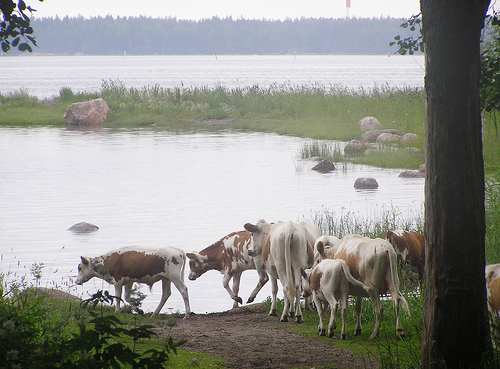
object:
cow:
[75, 245, 191, 321]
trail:
[216, 326, 228, 335]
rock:
[68, 221, 100, 233]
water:
[109, 203, 125, 224]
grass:
[0, 106, 64, 125]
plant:
[140, 332, 188, 369]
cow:
[300, 257, 366, 341]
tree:
[0, 0, 42, 58]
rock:
[63, 98, 111, 126]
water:
[165, 176, 213, 187]